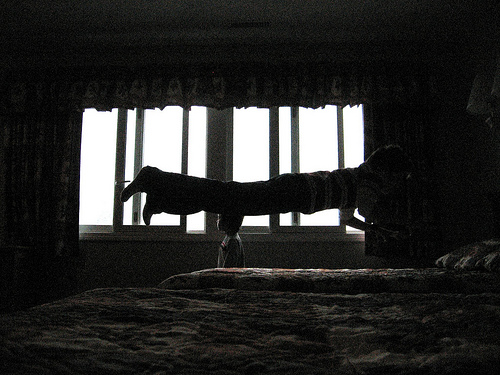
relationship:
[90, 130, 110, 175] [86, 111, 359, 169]
light shining through window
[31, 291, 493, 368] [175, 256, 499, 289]
bed next to bed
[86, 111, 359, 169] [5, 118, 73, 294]
window has curtain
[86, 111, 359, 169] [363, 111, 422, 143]
window has curtain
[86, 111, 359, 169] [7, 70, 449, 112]
window has valance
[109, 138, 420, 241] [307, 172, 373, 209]
man wearing shirt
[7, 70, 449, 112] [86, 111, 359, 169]
valance over window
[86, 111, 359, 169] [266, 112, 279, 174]
window has wood strip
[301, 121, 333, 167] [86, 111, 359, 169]
light coming through window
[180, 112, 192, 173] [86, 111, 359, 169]
wood strip supporting window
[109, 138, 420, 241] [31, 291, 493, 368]
man hovering over bed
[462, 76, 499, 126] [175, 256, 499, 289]
lamp mounted over bed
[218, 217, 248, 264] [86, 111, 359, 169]
boy next to window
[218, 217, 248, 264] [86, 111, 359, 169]
boy looking out window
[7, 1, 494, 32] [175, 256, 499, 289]
ceiling over bed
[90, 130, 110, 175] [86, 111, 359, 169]
light filtering through window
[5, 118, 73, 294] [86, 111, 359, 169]
curtain hanging on window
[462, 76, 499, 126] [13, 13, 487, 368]
lamp inside of bedroom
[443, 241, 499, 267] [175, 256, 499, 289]
pillow on top of bed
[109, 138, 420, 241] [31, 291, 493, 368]
man bouncing on bed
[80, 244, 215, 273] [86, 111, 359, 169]
wall below window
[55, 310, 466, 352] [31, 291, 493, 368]
blanket covering bed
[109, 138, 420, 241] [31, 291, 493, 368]
man leaping onto bed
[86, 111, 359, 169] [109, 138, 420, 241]
window behind man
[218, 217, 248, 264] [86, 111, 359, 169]
boy in front of window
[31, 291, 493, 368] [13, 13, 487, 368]
bed inside bedroom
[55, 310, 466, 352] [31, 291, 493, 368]
blanket on top of bed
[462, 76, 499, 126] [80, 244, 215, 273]
lamp attached to wall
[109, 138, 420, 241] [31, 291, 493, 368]
man over bed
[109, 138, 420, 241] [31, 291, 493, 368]
man falling into bed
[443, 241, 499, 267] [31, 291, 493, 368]
pillow on top of bed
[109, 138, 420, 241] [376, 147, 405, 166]
man has hair